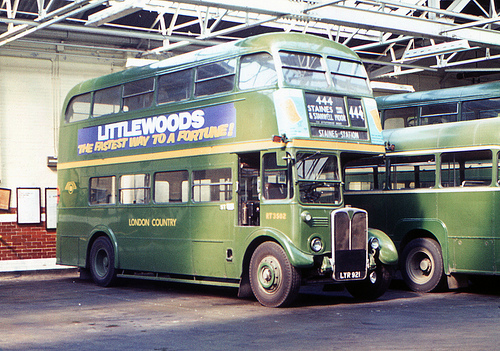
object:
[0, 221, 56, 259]
bricked area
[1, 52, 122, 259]
wall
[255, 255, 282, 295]
hubcap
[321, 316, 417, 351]
ground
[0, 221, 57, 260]
bricks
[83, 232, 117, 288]
back wheel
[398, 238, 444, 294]
back wheel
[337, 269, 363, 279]
plate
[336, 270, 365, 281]
numbers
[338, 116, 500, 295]
bus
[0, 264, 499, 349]
lot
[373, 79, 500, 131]
bus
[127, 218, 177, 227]
words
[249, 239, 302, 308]
wheel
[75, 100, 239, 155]
ad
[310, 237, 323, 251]
headlight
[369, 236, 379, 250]
headlight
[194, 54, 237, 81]
window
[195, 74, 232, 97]
window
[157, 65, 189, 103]
window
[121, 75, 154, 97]
window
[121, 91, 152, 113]
window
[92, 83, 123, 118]
window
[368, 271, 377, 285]
headlights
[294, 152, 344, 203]
windshield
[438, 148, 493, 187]
window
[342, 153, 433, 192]
window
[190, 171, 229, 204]
window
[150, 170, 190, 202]
window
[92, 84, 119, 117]
window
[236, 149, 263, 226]
window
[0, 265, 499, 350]
parking lot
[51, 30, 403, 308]
bus